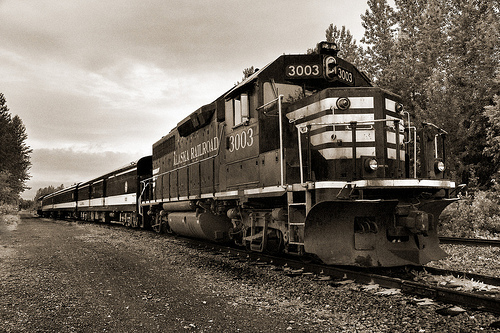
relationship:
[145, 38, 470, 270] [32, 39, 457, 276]
engine of train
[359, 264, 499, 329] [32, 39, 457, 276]
tracks of train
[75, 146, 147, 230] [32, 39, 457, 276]
car of train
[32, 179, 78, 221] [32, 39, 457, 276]
car of train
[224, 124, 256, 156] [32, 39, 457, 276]
number of train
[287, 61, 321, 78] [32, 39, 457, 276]
number of train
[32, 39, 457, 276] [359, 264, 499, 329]
train on tracks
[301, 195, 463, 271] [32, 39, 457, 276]
plow on train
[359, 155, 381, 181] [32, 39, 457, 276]
light on train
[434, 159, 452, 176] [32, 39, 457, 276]
light on train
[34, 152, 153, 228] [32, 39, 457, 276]
cabins of train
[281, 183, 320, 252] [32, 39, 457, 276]
ladder on train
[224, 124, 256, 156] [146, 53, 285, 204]
number on side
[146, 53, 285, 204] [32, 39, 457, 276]
side of train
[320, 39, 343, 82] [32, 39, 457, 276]
headlight on front of train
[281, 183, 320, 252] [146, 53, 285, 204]
ladder on side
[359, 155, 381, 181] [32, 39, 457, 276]
light on front of train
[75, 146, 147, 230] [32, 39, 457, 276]
front car of train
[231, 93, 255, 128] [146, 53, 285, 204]
window on side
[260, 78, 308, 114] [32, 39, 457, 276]
window on train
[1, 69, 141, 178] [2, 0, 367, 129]
clouds in sky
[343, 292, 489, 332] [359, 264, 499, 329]
gravel on tracks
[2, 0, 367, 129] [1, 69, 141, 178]
sky has clouds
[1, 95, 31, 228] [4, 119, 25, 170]
tree has leaves